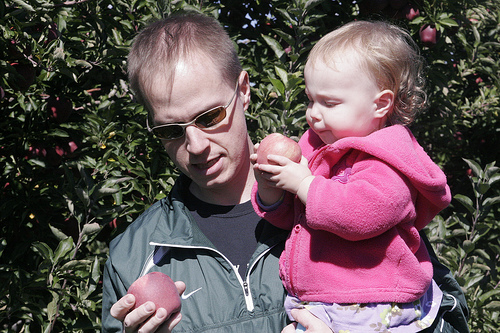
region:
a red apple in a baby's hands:
[250, 129, 305, 171]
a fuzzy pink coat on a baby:
[292, 131, 445, 293]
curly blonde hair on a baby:
[349, 32, 424, 129]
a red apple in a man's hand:
[112, 259, 209, 329]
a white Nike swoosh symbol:
[177, 285, 200, 300]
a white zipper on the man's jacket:
[160, 212, 291, 309]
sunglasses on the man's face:
[141, 101, 232, 136]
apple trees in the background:
[410, 5, 498, 136]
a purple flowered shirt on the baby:
[292, 294, 398, 331]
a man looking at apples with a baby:
[44, 9, 463, 322]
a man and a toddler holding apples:
[86, 12, 462, 332]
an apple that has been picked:
[117, 263, 194, 322]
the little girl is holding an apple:
[246, 21, 444, 331]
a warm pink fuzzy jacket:
[246, 128, 459, 302]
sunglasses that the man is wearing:
[132, 80, 245, 142]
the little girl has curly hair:
[292, 15, 440, 142]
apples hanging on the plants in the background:
[6, 35, 101, 175]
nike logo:
[179, 287, 206, 302]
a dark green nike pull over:
[91, 197, 298, 331]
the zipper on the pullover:
[148, 234, 295, 314]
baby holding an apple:
[256, 33, 421, 219]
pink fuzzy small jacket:
[321, 135, 441, 297]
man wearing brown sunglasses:
[107, 28, 248, 182]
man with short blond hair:
[128, 12, 260, 216]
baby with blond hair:
[302, 8, 415, 138]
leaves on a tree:
[0, 27, 115, 197]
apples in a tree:
[405, 7, 449, 53]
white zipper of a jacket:
[171, 211, 293, 323]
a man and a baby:
[132, 4, 452, 248]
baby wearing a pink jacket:
[239, 16, 464, 329]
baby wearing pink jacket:
[297, 24, 447, 318]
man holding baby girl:
[115, 10, 433, 327]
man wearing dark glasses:
[118, 41, 257, 202]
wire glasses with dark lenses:
[143, 85, 244, 147]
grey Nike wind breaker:
[93, 196, 300, 331]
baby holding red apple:
[252, 5, 464, 331]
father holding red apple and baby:
[91, 9, 387, 331]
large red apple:
[116, 267, 181, 332]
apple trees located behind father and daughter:
[30, 7, 462, 329]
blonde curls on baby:
[298, 18, 433, 140]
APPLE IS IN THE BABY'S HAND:
[257, 133, 296, 172]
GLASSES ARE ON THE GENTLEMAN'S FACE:
[147, 101, 233, 150]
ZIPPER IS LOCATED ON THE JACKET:
[238, 278, 267, 302]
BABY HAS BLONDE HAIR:
[335, 24, 425, 101]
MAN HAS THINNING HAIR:
[114, 27, 269, 94]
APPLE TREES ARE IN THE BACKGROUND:
[1, 0, 496, 331]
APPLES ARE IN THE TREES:
[9, 100, 78, 173]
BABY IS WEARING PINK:
[280, 124, 435, 309]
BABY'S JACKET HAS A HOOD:
[319, 125, 461, 213]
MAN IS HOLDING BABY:
[7, 4, 482, 329]